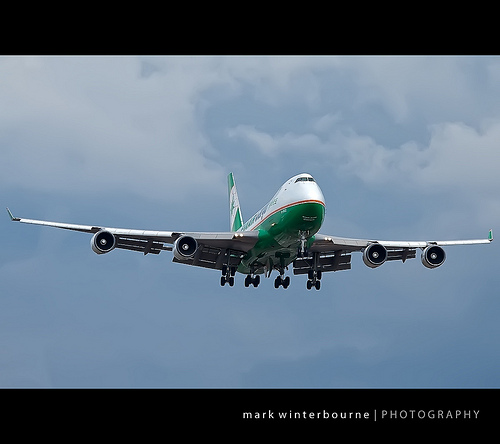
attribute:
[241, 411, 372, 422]
name — photographer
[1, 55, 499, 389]
skies — partly cloudy, cloudy, dark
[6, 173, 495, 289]
jet — white, green, red, landing, flying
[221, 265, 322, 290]
wheels — down, extended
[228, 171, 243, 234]
tail — green, white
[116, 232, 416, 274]
flaps — down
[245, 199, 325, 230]
stripe — red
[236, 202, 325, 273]
belly — green